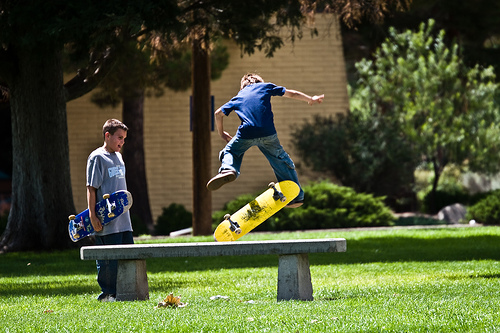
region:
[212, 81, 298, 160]
boy's shirt is blue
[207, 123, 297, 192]
boy is wearing blue jeans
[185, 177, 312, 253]
the skateboard is yellow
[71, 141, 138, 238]
boy's shirt is gray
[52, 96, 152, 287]
boy holding a skateboard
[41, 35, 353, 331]
boy is watching other boy skateboard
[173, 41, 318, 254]
boy is in the air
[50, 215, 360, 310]
bench made of concrete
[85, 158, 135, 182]
blue letters on shirt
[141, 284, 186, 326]
leaf on the grass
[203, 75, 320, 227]
A kid doing a trick on the skateboard.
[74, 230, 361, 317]
Bench in the park.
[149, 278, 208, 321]
Leaf on the grass.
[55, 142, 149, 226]
Boy holding the skateboard.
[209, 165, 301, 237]
The skateboard is yellow.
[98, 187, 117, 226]
The skateboard has wheels.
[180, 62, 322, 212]
The boy is in the air.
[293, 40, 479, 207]
Tree on the side of the building.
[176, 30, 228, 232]
Wooden pole with a sign.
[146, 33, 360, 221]
A building by the tree.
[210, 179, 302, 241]
Yellow skateboard in air.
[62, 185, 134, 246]
Blue skateboard being held.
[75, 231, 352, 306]
Cement bench on grass.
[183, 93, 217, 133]
Sign on pole.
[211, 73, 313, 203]
Boy wearing blue shirt.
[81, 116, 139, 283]
Boy wearing gray shirt.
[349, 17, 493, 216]
Tree in the background.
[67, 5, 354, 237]
Tan brick building in the background.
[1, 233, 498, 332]
Green grass on the ground.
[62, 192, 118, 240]
White wheels on the skateboard.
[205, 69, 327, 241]
This boy is skateboarding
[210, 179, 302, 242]
The skateboard is yellow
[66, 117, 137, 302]
This boy is holding a skateboard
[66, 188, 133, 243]
The skateboard is blue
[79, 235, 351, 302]
A stone bench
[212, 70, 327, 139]
The boy is wearing a blue shirt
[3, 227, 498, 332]
A grassy area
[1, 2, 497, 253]
Trees are growing in the background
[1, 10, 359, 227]
A brick building is in the background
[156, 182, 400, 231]
Bushes are growing near the building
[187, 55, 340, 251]
little boy doing a trick on his skateboard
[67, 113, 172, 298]
kid holding a skateboard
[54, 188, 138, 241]
skateboard under the arm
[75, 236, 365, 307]
concrete bench in the grass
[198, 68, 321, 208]
kid in the air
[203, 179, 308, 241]
bottom of the skateboard is yellow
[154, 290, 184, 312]
leaf on the grass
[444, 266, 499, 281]
shadow on the grass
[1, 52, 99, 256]
thick brown tree trunk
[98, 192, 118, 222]
wheels on the bottom of the board